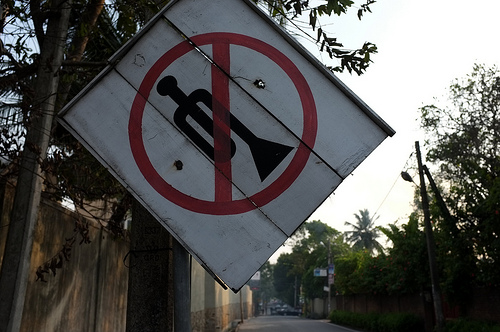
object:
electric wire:
[366, 136, 445, 228]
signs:
[313, 268, 328, 277]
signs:
[56, 0, 398, 295]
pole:
[324, 235, 334, 315]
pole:
[1, 0, 81, 331]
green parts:
[460, 66, 497, 125]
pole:
[414, 141, 461, 321]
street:
[228, 308, 360, 332]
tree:
[246, 0, 386, 74]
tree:
[0, 0, 181, 286]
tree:
[255, 63, 500, 331]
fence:
[0, 162, 255, 332]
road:
[225, 306, 358, 332]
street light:
[401, 141, 484, 329]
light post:
[412, 141, 449, 331]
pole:
[125, 199, 184, 331]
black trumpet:
[156, 74, 295, 183]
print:
[129, 29, 319, 215]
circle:
[128, 32, 317, 215]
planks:
[58, 0, 399, 294]